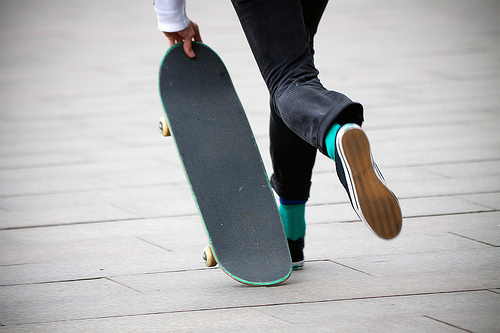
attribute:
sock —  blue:
[279, 199, 305, 241]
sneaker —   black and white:
[287, 238, 304, 269]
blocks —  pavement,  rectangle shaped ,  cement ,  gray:
[391, 5, 499, 331]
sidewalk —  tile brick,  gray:
[20, 102, 160, 307]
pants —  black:
[222, 2, 364, 171]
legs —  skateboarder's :
[223, 2, 383, 255]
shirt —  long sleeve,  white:
[153, 2, 189, 31]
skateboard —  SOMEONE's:
[120, 17, 279, 280]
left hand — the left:
[162, 16, 204, 59]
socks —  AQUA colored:
[270, 183, 315, 264]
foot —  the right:
[329, 120, 406, 247]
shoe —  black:
[282, 234, 314, 271]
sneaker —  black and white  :
[334, 122, 405, 241]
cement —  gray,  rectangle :
[108, 260, 188, 331]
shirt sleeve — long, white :
[153, 0, 193, 34]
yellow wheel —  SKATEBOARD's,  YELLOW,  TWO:
[155, 115, 172, 137]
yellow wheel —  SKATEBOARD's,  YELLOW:
[201, 245, 218, 266]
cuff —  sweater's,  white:
[152, 0, 190, 33]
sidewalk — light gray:
[22, 38, 492, 291]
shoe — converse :
[334, 124, 403, 240]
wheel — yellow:
[152, 112, 179, 141]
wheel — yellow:
[196, 244, 218, 274]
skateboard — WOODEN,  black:
[153, 36, 296, 287]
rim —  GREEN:
[159, 38, 291, 286]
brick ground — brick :
[12, 217, 497, 329]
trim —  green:
[157, 33, 292, 292]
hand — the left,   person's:
[158, 13, 209, 55]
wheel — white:
[200, 244, 217, 270]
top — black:
[159, 34, 290, 282]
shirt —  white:
[155, 1, 191, 34]